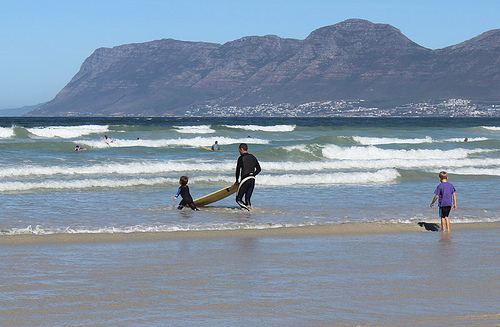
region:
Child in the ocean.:
[429, 170, 463, 229]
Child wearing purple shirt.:
[430, 179, 460, 206]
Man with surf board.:
[190, 141, 265, 213]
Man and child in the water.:
[170, 145, 265, 212]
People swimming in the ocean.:
[71, 121, 473, 159]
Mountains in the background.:
[31, 20, 496, 118]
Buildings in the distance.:
[161, 94, 499, 122]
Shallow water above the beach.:
[6, 221, 495, 326]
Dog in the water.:
[407, 217, 448, 233]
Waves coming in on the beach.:
[5, 118, 493, 234]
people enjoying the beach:
[57, 115, 469, 264]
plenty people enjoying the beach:
[40, 116, 480, 286]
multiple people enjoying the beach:
[43, 103, 483, 260]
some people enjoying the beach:
[45, 100, 486, 306]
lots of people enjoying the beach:
[45, 103, 492, 301]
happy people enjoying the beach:
[39, 104, 481, 275]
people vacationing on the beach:
[19, 73, 480, 304]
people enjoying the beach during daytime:
[0, 20, 477, 281]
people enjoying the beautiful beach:
[35, 68, 470, 278]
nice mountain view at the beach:
[19, 7, 488, 132]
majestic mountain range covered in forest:
[47, 25, 498, 99]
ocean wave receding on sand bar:
[11, 220, 353, 244]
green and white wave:
[8, 121, 97, 140]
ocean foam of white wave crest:
[328, 146, 447, 162]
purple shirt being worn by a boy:
[428, 178, 460, 207]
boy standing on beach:
[425, 167, 461, 239]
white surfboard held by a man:
[178, 174, 240, 208]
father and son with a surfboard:
[172, 141, 277, 221]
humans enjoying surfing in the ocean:
[69, 121, 221, 155]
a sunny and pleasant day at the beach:
[64, 103, 468, 259]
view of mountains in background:
[1, 12, 498, 120]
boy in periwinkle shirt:
[432, 172, 462, 240]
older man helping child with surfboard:
[171, 139, 268, 212]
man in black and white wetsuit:
[230, 140, 262, 213]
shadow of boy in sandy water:
[415, 211, 440, 236]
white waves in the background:
[0, 120, 497, 190]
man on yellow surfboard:
[195, 140, 220, 155]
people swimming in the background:
[75, 126, 151, 151]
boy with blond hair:
[426, 165, 457, 230]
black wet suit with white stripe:
[230, 140, 265, 210]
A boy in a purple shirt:
[430, 163, 462, 237]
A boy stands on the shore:
[425, 167, 470, 247]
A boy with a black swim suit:
[165, 167, 211, 223]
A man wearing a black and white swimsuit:
[224, 136, 271, 227]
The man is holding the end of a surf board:
[184, 137, 293, 229]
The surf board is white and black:
[177, 181, 264, 224]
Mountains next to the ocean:
[75, 22, 475, 137]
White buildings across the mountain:
[149, 86, 478, 122]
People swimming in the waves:
[41, 110, 467, 182]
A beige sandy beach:
[26, 177, 474, 315]